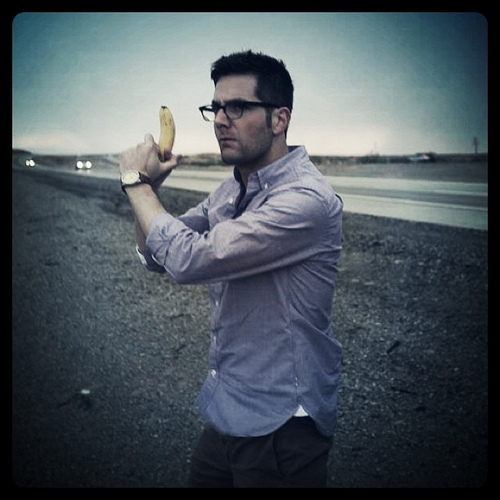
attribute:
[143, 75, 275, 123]
glasses — black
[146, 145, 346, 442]
purple shirt — light purple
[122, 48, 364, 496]
man — alert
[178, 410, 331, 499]
pants — dark pair